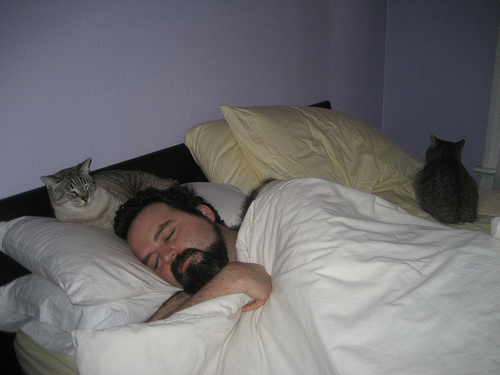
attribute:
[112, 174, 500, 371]
man — sleeping, asleep, laying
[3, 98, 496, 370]
bed — wooden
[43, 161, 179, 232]
cat — sleeping, gray, white, light gray, laying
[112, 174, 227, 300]
head — man's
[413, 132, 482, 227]
cat — laying, dark gray, black, sleeping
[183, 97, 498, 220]
sheets — yellow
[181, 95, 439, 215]
pillows — yellow, white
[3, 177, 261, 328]
pillows — white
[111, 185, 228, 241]
hair — dark, curly, brown, black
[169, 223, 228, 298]
beard — black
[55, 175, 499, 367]
bed-cover — white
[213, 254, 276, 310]
hand — man's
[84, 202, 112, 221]
belly — white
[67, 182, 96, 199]
eyes — closed, cat's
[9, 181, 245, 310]
pillow — white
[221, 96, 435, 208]
pillowcase — yellow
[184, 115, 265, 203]
pillowcase — yellow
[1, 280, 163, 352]
pillow — white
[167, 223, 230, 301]
hair — facial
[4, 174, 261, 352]
group — pillows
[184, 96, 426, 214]
group — pillows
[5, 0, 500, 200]
wall — white